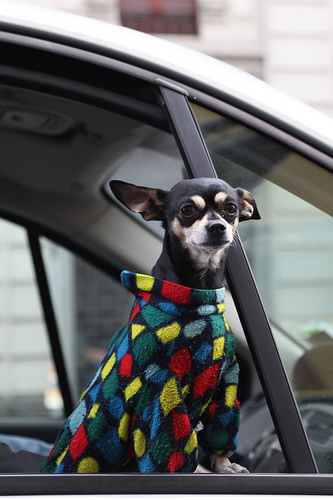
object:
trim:
[159, 79, 328, 476]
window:
[186, 96, 333, 473]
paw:
[215, 461, 250, 474]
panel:
[245, 406, 332, 474]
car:
[1, 0, 333, 497]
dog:
[38, 177, 264, 474]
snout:
[191, 209, 230, 248]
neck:
[162, 231, 227, 289]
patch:
[188, 244, 226, 268]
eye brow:
[190, 195, 206, 208]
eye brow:
[215, 191, 228, 204]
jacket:
[36, 268, 244, 476]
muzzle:
[191, 210, 234, 251]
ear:
[105, 178, 168, 223]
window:
[1, 39, 292, 477]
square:
[123, 375, 143, 400]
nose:
[206, 215, 227, 238]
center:
[202, 210, 223, 221]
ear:
[234, 185, 261, 223]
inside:
[239, 199, 254, 218]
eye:
[178, 202, 198, 216]